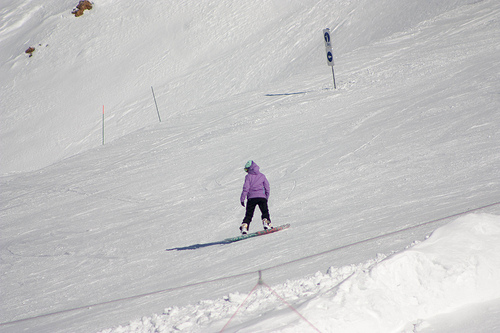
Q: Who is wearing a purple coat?
A: A little girl on a snowboard.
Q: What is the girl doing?
A: Snowboarding down hill.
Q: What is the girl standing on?
A: A snowboard.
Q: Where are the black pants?
A: On the little girl.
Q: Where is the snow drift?
A: Behind the girl.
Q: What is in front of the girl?
A: Three metal poles.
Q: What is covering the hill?
A: Snow.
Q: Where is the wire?
A: In front of the snow drift.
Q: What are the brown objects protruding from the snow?
A: Rocks.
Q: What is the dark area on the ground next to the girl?
A: Her shadow.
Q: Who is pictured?
A: A woman.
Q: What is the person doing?
A: Snowboarding.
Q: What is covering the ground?
A: Snow.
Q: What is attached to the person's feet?
A: Snowboard.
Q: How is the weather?
A: Clear.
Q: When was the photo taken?
A: During day hours.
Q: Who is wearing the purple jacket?
A: The snowboarder.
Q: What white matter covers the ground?
A: Snow.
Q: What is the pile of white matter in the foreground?
A: Snow.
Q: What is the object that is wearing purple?
A: Snowboarder.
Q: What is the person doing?
A: Snowboarding down hill.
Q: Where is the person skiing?
A: A slope.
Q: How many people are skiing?
A: One.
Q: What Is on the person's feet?
A: Skis.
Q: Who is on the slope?
A: A skier.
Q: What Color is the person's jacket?
A: Purple.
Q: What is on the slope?
A: Snow.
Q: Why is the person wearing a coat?
A: It's cold.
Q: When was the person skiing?
A: Daytime.